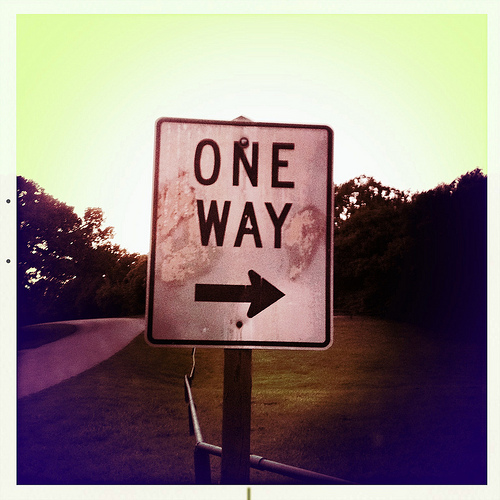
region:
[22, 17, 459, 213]
The sky is clear.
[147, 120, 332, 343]
The sign is white.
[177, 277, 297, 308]
The arrow is black.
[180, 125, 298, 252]
The lettering is black.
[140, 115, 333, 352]
The edging is black.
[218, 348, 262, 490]
The pole is wooden.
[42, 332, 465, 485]
The grass is green.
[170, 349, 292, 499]
The fence is metal.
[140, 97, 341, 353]
The sign says one way.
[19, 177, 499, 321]
The trees are leafy.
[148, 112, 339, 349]
street sign on pole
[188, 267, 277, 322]
arrow on street sign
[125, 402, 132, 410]
patch of green grass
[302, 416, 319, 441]
patch of green grass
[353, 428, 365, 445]
patch of green grass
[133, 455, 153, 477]
patch of green grass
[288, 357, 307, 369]
patch of green grass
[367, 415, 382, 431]
patch of green grass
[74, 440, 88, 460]
patch of green grass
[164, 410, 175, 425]
patch of green grass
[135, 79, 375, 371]
one way sign with an arrow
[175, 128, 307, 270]
black letters on sign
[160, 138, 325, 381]
sign is white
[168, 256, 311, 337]
sign has a black arrow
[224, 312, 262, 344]
sign has some metal bolts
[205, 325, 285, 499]
sign has a dark post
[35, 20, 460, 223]
bright sky behind sign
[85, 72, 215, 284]
sun is yellow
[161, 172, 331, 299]
sign is very dirty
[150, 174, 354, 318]
sign has black marks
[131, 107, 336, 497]
This is a sign post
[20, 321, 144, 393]
The sidewalk by the field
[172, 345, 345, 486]
A fence in the field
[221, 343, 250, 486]
A wooden post holding a sign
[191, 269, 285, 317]
An arrow on the sign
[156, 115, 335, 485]
A One Way sign near a grassy field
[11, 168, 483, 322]
Trees behind the sign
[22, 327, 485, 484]
A grassy field behind the sign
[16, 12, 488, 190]
The sky above the field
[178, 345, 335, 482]
A railing on the fence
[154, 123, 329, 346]
The sign has a rectangular shape